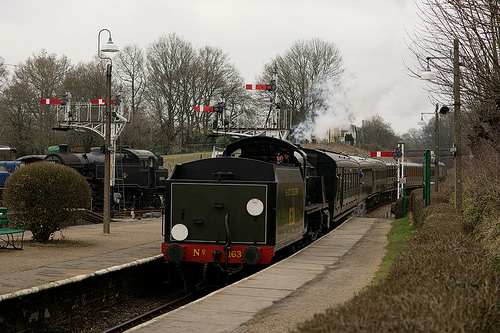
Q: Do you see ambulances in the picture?
A: No, there are no ambulances.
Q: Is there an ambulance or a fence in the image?
A: No, there are no ambulances or fences.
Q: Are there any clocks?
A: No, there are no clocks.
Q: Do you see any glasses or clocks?
A: No, there are no clocks or glasses.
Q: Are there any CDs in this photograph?
A: No, there are no cds.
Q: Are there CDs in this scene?
A: No, there are no cds.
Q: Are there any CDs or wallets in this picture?
A: No, there are no CDs or wallets.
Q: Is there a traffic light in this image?
A: Yes, there is a traffic light.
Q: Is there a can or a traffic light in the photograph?
A: Yes, there is a traffic light.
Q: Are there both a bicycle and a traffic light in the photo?
A: No, there is a traffic light but no bicycles.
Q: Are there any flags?
A: No, there are no flags.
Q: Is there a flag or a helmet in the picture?
A: No, there are no flags or helmets.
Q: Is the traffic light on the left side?
A: Yes, the traffic light is on the left of the image.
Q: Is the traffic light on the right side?
A: No, the traffic light is on the left of the image.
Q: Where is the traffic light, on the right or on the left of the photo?
A: The traffic light is on the left of the image.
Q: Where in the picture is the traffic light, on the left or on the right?
A: The traffic light is on the left of the image.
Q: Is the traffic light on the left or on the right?
A: The traffic light is on the left of the image.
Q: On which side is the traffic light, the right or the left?
A: The traffic light is on the left of the image.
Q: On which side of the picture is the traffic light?
A: The traffic light is on the left of the image.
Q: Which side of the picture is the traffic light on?
A: The traffic light is on the left of the image.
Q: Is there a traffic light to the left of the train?
A: Yes, there is a traffic light to the left of the train.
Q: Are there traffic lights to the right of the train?
A: No, the traffic light is to the left of the train.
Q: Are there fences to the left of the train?
A: No, there is a traffic light to the left of the train.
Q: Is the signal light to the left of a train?
A: Yes, the signal light is to the left of a train.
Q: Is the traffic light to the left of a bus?
A: No, the traffic light is to the left of a train.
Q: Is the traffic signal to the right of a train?
A: No, the traffic signal is to the left of a train.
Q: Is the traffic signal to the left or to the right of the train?
A: The traffic signal is to the left of the train.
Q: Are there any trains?
A: Yes, there is a train.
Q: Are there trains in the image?
A: Yes, there is a train.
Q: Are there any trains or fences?
A: Yes, there is a train.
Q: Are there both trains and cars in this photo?
A: Yes, there are both a train and a car.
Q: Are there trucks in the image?
A: No, there are no trucks.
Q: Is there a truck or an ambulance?
A: No, there are no trucks or ambulances.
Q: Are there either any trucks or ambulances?
A: No, there are no trucks or ambulances.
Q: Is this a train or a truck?
A: This is a train.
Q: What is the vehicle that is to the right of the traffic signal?
A: The vehicle is a train.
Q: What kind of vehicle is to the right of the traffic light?
A: The vehicle is a train.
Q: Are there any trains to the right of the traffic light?
A: Yes, there is a train to the right of the traffic light.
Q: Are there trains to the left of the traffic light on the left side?
A: No, the train is to the right of the traffic light.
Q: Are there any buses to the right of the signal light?
A: No, there is a train to the right of the signal light.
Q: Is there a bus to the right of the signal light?
A: No, there is a train to the right of the signal light.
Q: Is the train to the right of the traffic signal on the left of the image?
A: Yes, the train is to the right of the traffic light.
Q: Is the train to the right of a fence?
A: No, the train is to the right of the traffic light.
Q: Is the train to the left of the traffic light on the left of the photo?
A: No, the train is to the right of the signal light.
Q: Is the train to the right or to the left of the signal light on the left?
A: The train is to the right of the traffic light.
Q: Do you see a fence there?
A: No, there are no fences.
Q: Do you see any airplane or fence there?
A: No, there are no fences or airplanes.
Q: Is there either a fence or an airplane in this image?
A: No, there are no fences or airplanes.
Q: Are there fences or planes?
A: No, there are no fences or planes.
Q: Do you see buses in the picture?
A: No, there are no buses.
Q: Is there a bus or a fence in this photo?
A: No, there are no buses or fences.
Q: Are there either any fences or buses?
A: No, there are no buses or fences.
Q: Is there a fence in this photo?
A: No, there are no fences.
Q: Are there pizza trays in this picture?
A: No, there are no pizza trays.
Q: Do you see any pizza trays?
A: No, there are no pizza trays.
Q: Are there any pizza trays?
A: No, there are no pizza trays.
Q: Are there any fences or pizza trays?
A: No, there are no pizza trays or fences.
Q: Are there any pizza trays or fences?
A: No, there are no pizza trays or fences.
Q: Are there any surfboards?
A: No, there are no surfboards.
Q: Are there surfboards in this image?
A: No, there are no surfboards.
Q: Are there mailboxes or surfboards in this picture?
A: No, there are no surfboards or mailboxes.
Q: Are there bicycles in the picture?
A: No, there are no bicycles.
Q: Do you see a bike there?
A: No, there are no bikes.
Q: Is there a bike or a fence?
A: No, there are no bikes or fences.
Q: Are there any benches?
A: Yes, there is a bench.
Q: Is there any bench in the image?
A: Yes, there is a bench.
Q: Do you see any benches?
A: Yes, there is a bench.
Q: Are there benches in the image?
A: Yes, there is a bench.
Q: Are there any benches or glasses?
A: Yes, there is a bench.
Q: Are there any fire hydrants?
A: No, there are no fire hydrants.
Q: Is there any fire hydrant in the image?
A: No, there are no fire hydrants.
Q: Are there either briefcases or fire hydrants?
A: No, there are no fire hydrants or briefcases.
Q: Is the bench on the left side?
A: Yes, the bench is on the left of the image.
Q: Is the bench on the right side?
A: No, the bench is on the left of the image.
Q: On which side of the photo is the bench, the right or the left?
A: The bench is on the left of the image.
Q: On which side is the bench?
A: The bench is on the left of the image.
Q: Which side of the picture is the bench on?
A: The bench is on the left of the image.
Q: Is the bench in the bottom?
A: Yes, the bench is in the bottom of the image.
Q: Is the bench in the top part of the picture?
A: No, the bench is in the bottom of the image.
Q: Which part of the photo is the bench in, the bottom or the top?
A: The bench is in the bottom of the image.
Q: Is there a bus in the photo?
A: No, there are no buses.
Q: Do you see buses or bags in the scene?
A: No, there are no buses or bags.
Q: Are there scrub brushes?
A: No, there are no scrub brushes.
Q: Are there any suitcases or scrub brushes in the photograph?
A: No, there are no scrub brushes or suitcases.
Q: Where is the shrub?
A: The shrub is on the sidewalk.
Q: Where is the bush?
A: The shrub is on the sidewalk.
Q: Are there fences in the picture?
A: No, there are no fences.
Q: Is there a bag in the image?
A: No, there are no bags.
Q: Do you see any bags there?
A: No, there are no bags.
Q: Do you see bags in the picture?
A: No, there are no bags.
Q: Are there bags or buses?
A: No, there are no bags or buses.